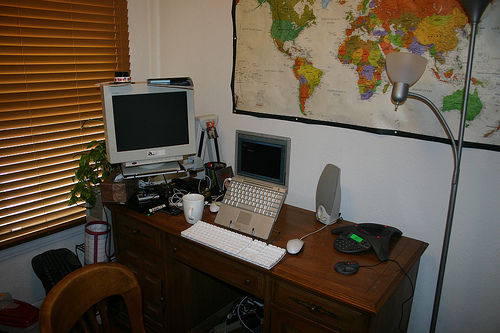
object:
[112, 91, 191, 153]
screen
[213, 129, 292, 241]
laptop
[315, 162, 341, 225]
speaker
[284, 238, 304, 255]
mouse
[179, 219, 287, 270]
keyboard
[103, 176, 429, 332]
desk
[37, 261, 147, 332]
chair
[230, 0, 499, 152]
map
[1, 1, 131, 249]
window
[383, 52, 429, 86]
lamp shade